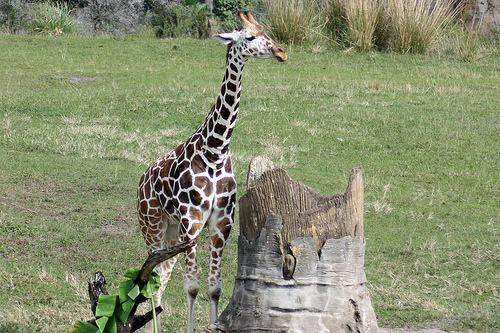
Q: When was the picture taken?
A: Daytime.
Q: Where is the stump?
A: In front of giraffe.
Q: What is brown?
A: Stump.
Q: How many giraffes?
A: One.